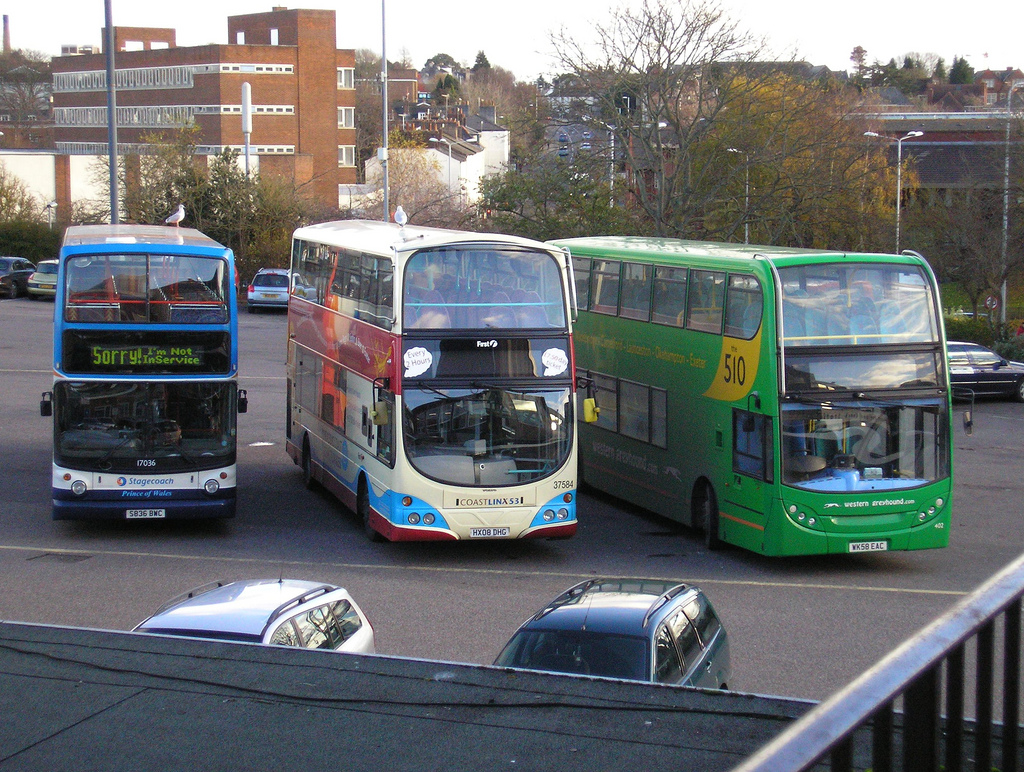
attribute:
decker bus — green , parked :
[582, 199, 965, 578]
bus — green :
[615, 163, 987, 647]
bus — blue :
[64, 182, 306, 623]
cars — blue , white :
[144, 560, 834, 740]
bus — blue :
[244, 189, 634, 609]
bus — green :
[533, 128, 964, 626]